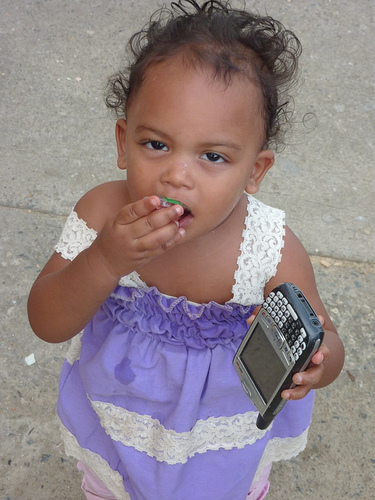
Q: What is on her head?
A: Hair.